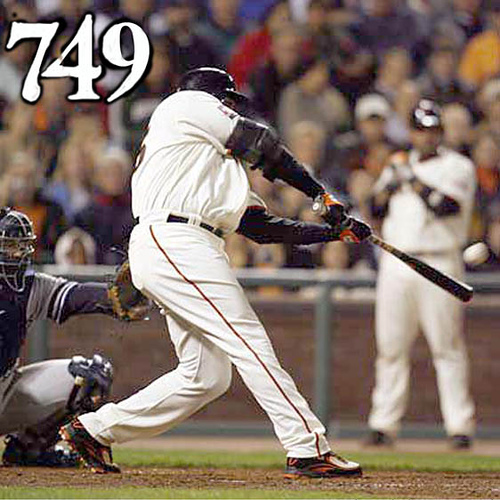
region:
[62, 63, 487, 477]
baseball player swing a bat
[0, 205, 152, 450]
catcher holding a catcher's mitt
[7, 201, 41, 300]
face mask on the catcher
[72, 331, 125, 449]
knee pads on the catcher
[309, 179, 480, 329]
bat hitting the ball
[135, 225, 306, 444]
strip on the player's pants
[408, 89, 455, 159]
player wearing batting helmet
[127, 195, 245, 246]
belt on the baseball player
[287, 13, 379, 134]
shoe on the baseball player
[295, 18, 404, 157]
people in the stands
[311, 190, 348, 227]
the glove of a player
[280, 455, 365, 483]
the shoe of a man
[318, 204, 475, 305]
a black baseball bat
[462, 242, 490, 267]
a small white baseball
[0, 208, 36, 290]
a facemask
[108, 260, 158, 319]
a brown catcher's glove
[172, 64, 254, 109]
a black baseball helmet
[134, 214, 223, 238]
a man's black belt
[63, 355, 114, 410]
part of a knee pad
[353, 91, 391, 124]
a white baseball cap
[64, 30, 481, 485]
batter taking a swing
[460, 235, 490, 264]
small white baseball in motion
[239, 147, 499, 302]
bat extended in front of the body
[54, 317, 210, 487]
leg is extended back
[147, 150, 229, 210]
wrinkles in the shirt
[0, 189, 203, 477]
catcher crouched behind the batter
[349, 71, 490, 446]
next batter watching the action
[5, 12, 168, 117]
large white number 749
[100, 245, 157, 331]
glove is open and waiting for the ball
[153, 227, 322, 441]
red stripe along the side of the pants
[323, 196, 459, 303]
Baseball bat in hitters hand.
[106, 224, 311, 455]
Baseball player pants with red cording.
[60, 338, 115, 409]
Catcher knee protection padding.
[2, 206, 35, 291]
Catcher's protection mask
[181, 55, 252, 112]
Baseball player's hard helmet.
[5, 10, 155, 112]
Number 749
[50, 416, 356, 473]
Baseball player's athletic shoes with cleats.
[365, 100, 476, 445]
Baseball player waiting for his time to bat.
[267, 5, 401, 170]
People in bleachers at baseball game.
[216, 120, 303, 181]
Baseball player with elbow protection pad.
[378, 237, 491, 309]
Baseball bat hitting baseball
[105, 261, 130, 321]
Brown catchers mitt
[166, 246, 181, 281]
Thin red stripe on pants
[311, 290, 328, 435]
Grey metal safety rail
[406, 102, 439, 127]
Black batters safety helmet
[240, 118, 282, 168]
Thick black elbow pad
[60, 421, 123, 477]
Pair of red and black cleats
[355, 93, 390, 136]
Guy in background with white hat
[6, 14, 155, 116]
White number 749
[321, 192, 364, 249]
Black and orange batter gloves